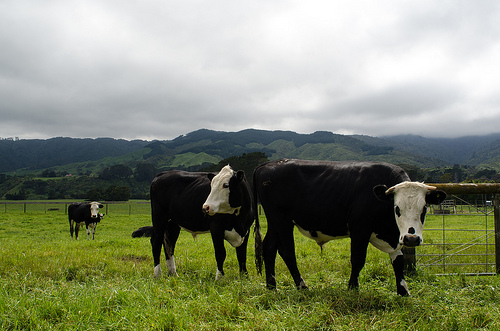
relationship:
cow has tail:
[251, 157, 450, 296] [250, 163, 266, 277]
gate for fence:
[411, 192, 498, 276] [1, 200, 495, 218]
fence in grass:
[1, 200, 495, 218] [3, 214, 499, 331]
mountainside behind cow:
[2, 127, 500, 198] [67, 201, 103, 240]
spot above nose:
[407, 223, 418, 235] [402, 234, 422, 247]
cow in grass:
[67, 199, 102, 240] [3, 214, 499, 331]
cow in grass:
[143, 161, 255, 287] [3, 214, 499, 331]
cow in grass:
[251, 157, 450, 296] [3, 214, 499, 331]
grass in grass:
[3, 214, 499, 331] [3, 214, 499, 331]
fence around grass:
[1, 200, 495, 218] [3, 214, 499, 331]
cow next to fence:
[67, 199, 102, 240] [1, 200, 495, 218]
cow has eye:
[143, 161, 255, 287] [221, 183, 232, 189]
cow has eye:
[251, 157, 450, 296] [394, 207, 400, 217]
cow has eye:
[251, 157, 450, 296] [422, 206, 426, 218]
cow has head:
[67, 199, 102, 240] [88, 200, 104, 220]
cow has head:
[143, 161, 255, 287] [200, 164, 244, 216]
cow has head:
[251, 157, 450, 296] [383, 178, 439, 245]